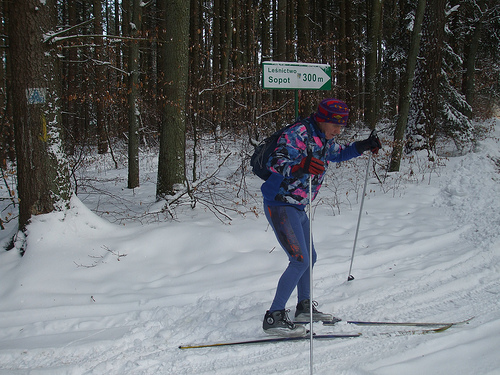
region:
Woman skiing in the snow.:
[232, 81, 394, 351]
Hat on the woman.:
[312, 97, 352, 147]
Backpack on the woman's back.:
[246, 95, 303, 185]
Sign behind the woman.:
[256, 52, 333, 95]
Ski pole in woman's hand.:
[298, 156, 331, 373]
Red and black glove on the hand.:
[292, 148, 332, 180]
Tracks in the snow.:
[1, 206, 497, 373]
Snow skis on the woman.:
[178, 308, 448, 360]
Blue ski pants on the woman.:
[249, 96, 361, 331]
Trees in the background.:
[2, 1, 498, 238]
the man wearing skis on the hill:
[247, 94, 387, 329]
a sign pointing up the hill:
[253, 57, 335, 98]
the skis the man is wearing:
[181, 308, 473, 355]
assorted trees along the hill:
[7, 6, 498, 167]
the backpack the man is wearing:
[251, 125, 321, 176]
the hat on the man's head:
[315, 93, 352, 121]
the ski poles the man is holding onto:
[301, 143, 376, 373]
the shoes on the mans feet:
[260, 299, 338, 342]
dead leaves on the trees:
[53, 78, 175, 110]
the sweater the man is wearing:
[257, 123, 325, 206]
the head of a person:
[294, 79, 391, 145]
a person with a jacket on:
[254, 83, 394, 213]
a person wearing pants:
[248, 112, 448, 334]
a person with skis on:
[190, 96, 452, 359]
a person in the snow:
[203, 57, 425, 354]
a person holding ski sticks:
[256, 93, 470, 363]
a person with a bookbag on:
[242, 55, 414, 219]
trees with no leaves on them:
[125, 5, 473, 162]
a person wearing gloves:
[288, 110, 428, 201]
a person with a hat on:
[277, 71, 404, 168]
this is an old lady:
[238, 85, 362, 325]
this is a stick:
[299, 241, 323, 302]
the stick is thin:
[339, 188, 380, 237]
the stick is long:
[334, 178, 376, 252]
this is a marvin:
[319, 100, 347, 120]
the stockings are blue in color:
[267, 210, 308, 297]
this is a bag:
[243, 136, 275, 178]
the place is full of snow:
[96, 238, 174, 308]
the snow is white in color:
[70, 247, 166, 364]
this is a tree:
[147, 18, 197, 120]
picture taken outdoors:
[11, 10, 498, 365]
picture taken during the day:
[31, 26, 488, 373]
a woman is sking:
[232, 69, 417, 363]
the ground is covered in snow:
[57, 256, 138, 343]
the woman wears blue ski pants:
[282, 196, 307, 260]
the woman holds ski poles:
[298, 138, 400, 296]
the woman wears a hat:
[314, 99, 345, 119]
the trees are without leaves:
[57, 40, 169, 125]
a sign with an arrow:
[261, 58, 336, 86]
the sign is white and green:
[264, 62, 331, 86]